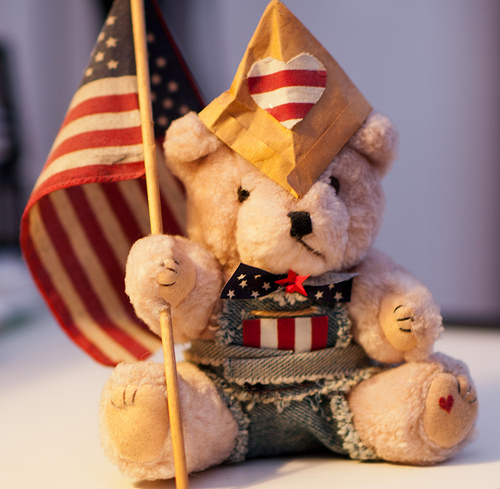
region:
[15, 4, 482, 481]
stuffed tedy bear holding an American Flag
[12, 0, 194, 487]
mini American Flag with wooden stick for the pole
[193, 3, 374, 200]
small paper hat with red striped heart in center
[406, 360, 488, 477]
teddy bear foor with heart on the bottom of the paw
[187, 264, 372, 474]
small denim teddy bear overalls with star and stripe design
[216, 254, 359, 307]
red and blue star and stripe bowtie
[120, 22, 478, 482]
teddy bear with a paper hat and a star and stripe denim outfit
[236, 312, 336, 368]
pocket on front of overalls with red stripes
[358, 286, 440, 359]
stuffed teddy bear paw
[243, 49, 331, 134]
cloth , red striped, heart on front of paper hat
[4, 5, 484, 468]
Stuffed bear holding an American flag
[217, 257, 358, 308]
Navy bow tie with stars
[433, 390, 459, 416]
Heart stitched onto bear's paw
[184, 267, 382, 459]
Bear's denim overalls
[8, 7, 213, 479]
American flag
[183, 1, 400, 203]
Military-style cap with red and white striped heart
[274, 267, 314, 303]
Shiny red sequin star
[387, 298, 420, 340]
Black stitching on paw to indicate toes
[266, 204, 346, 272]
Black stitching forming nose and mouth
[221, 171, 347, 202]
Black stitching forming bear's eyes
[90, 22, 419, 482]
the teddy bear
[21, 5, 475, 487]
teddy bear with American colors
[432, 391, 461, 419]
red heart on teddy bear's paw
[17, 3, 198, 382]
American flag in bear's hand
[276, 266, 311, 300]
red star on clothes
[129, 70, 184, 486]
wooden dowel for the flag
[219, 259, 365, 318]
blue ribbon on bear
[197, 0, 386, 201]
paper hat on bear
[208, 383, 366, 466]
denim shorts on bear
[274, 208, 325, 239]
black nose on bear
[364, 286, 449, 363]
left front paw of bear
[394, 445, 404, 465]
leg of a doll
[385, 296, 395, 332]
left hand of a doll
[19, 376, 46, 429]
part of a table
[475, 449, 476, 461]
top of a table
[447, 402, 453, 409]
part of a love heart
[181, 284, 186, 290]
left hand of a doll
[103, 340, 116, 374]
tip of a flag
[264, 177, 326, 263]
face of a doll